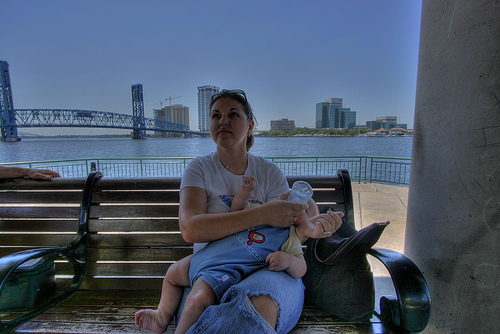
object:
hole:
[236, 290, 285, 333]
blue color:
[184, 267, 305, 333]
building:
[316, 97, 357, 129]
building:
[197, 85, 221, 131]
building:
[366, 115, 407, 130]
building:
[152, 96, 189, 135]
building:
[271, 118, 295, 131]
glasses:
[211, 89, 248, 102]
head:
[208, 88, 254, 148]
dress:
[189, 225, 291, 300]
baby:
[133, 176, 319, 334]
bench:
[0, 162, 432, 318]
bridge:
[0, 60, 210, 142]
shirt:
[281, 225, 304, 255]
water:
[253, 137, 398, 159]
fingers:
[302, 211, 344, 237]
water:
[0, 137, 414, 188]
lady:
[134, 88, 343, 334]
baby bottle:
[288, 181, 313, 204]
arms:
[178, 170, 262, 244]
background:
[11, 109, 208, 139]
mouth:
[285, 197, 294, 203]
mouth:
[217, 130, 232, 135]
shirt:
[179, 152, 290, 255]